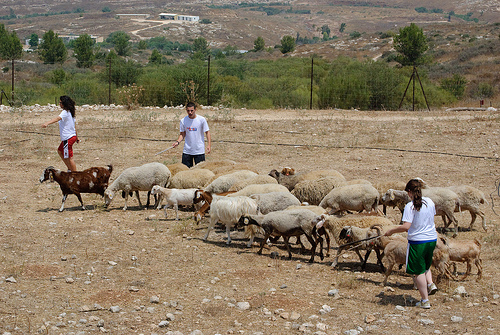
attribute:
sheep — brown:
[38, 160, 113, 211]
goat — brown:
[33, 162, 115, 215]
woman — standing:
[382, 179, 440, 311]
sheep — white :
[100, 160, 170, 212]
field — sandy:
[1, 99, 497, 333]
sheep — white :
[121, 161, 209, 208]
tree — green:
[386, 23, 431, 110]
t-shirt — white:
[180, 116, 208, 155]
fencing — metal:
[0, 51, 497, 111]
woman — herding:
[384, 179, 444, 306]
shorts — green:
[399, 235, 439, 284]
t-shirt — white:
[394, 193, 442, 240]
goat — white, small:
[146, 179, 203, 214]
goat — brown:
[42, 162, 112, 212]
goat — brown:
[36, 159, 113, 211]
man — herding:
[166, 100, 214, 155]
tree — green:
[95, 41, 117, 101]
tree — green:
[70, 32, 95, 69]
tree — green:
[0, 29, 21, 96]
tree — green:
[185, 34, 209, 56]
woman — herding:
[49, 90, 86, 172]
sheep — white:
[234, 206, 326, 257]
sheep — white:
[190, 182, 263, 240]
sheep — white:
[336, 224, 397, 254]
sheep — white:
[434, 231, 484, 277]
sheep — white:
[144, 177, 203, 217]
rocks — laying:
[0, 256, 490, 333]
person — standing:
[384, 175, 437, 310]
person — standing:
[174, 101, 214, 169]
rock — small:
[236, 299, 251, 310]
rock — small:
[320, 303, 331, 312]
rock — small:
[325, 288, 339, 298]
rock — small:
[421, 316, 434, 326]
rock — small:
[4, 275, 16, 285]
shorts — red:
[56, 133, 76, 156]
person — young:
[381, 177, 439, 311]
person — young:
[172, 103, 212, 167]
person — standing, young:
[43, 94, 79, 168]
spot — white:
[68, 177, 73, 183]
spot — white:
[75, 179, 79, 184]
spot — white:
[88, 180, 94, 187]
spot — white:
[91, 170, 97, 178]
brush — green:
[225, 56, 424, 115]